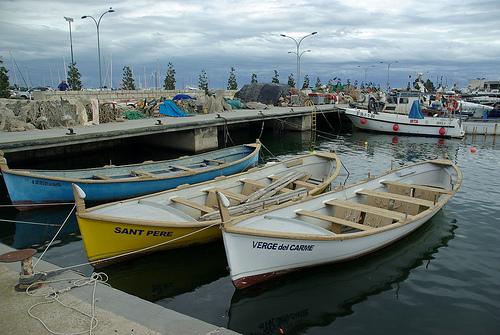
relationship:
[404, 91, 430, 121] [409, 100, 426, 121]
man with shirt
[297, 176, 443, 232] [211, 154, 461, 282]
bench center boat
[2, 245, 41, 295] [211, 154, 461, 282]
post tied to boat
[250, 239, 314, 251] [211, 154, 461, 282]
name on boat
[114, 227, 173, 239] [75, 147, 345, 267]
name on boat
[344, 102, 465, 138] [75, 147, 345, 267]
boat behind boat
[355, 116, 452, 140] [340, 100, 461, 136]
balloons beside boat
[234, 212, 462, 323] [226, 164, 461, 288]
reflection of boat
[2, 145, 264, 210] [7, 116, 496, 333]
boat in water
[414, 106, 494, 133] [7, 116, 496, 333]
boat in water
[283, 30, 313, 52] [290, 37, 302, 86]
light on pole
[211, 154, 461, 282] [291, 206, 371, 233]
boat with seat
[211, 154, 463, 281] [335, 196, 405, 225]
boat with seat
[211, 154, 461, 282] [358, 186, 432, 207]
boat with seat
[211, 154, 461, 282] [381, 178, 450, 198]
boat with seat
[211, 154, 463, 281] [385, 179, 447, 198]
boat with seat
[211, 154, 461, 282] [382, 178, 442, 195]
boat with seat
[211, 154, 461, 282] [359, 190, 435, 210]
boat with seat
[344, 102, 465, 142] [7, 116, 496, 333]
boat on water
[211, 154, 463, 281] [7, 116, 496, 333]
boat in water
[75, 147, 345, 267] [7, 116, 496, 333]
boat in water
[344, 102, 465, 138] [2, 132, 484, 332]
boat in water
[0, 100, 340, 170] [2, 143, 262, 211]
dock next to boat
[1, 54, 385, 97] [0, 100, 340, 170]
trees near dock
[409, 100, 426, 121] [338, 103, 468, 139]
shirt on boat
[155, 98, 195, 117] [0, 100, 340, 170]
tarp on dock